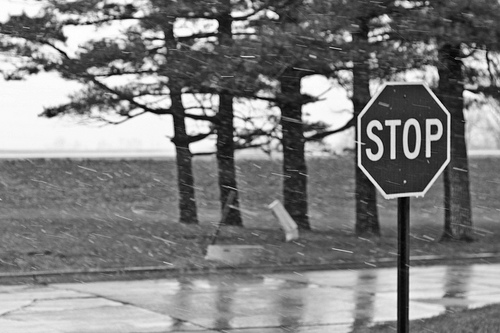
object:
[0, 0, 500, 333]
photo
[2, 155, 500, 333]
grass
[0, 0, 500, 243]
trees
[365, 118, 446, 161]
caps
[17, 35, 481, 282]
air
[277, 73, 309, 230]
trunk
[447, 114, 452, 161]
white perimeter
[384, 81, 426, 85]
white perimeter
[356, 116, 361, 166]
white perimeter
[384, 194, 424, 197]
white perimeter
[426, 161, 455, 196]
white perimeter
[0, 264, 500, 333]
crack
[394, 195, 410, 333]
pole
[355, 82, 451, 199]
border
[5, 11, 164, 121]
branches